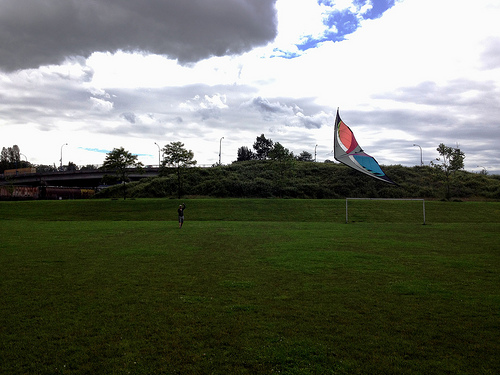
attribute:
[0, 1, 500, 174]
sky — cloudy, bright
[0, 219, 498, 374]
soccer field — green, grassy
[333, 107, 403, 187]
kite — red white, blue, flying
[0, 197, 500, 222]
slope — grassy